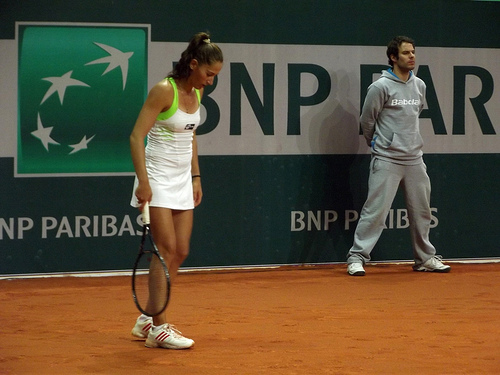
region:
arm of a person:
[126, 110, 162, 180]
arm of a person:
[183, 125, 210, 187]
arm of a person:
[365, 102, 385, 147]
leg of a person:
[142, 210, 174, 307]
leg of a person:
[357, 154, 393, 249]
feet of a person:
[143, 324, 205, 354]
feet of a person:
[318, 251, 379, 296]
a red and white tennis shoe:
[144, 322, 195, 349]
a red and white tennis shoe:
[132, 313, 153, 338]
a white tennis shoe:
[345, 263, 365, 275]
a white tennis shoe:
[418, 258, 448, 273]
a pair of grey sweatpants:
[346, 155, 436, 269]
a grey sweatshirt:
[357, 70, 427, 163]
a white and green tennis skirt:
[130, 78, 201, 213]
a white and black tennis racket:
[130, 204, 172, 316]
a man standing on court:
[344, 35, 449, 276]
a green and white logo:
[19, 23, 146, 176]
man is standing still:
[343, 27, 449, 274]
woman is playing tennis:
[119, 21, 226, 361]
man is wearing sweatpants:
[346, 25, 456, 275]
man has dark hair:
[340, 32, 450, 272]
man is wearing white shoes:
[340, 31, 457, 281]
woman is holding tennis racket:
[120, 22, 210, 364]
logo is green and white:
[13, 18, 155, 173]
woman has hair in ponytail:
[122, 27, 217, 352]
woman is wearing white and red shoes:
[125, 25, 222, 353]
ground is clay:
[2, 242, 497, 357]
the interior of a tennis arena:
[0, 0, 499, 373]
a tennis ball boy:
[346, 35, 451, 275]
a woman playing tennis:
[129, 32, 222, 349]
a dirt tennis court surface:
[0, 261, 498, 373]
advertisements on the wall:
[0, 0, 499, 280]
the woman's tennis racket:
[130, 200, 171, 317]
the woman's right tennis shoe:
[142, 322, 194, 349]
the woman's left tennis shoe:
[130, 317, 152, 337]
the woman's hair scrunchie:
[202, 38, 210, 44]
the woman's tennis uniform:
[129, 76, 200, 210]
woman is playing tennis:
[118, 27, 229, 354]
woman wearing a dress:
[130, 74, 205, 210]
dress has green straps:
[153, 72, 204, 120]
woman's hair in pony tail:
[163, 29, 225, 86]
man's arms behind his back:
[343, 32, 453, 277]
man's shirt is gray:
[356, 67, 428, 169]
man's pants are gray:
[345, 153, 442, 264]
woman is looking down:
[163, 23, 225, 92]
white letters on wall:
[0, 201, 449, 240]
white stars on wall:
[27, 34, 136, 158]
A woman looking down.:
[116, 24, 226, 360]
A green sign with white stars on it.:
[8, 16, 154, 179]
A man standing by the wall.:
[342, 29, 457, 286]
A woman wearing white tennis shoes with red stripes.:
[113, 308, 211, 357]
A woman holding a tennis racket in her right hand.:
[115, 175, 177, 322]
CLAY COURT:
[8, 251, 498, 369]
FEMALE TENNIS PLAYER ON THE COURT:
[123, 21, 238, 351]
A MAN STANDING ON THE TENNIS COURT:
[336, 32, 451, 277]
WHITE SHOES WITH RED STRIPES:
[130, 311, 195, 351]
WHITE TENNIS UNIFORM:
[113, 70, 209, 220]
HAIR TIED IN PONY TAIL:
[166, 33, 224, 91]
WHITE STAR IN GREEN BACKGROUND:
[36, 63, 87, 110]